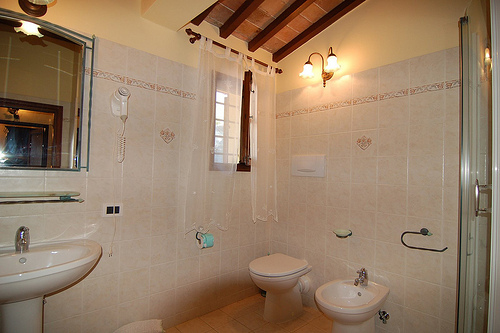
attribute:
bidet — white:
[318, 262, 393, 329]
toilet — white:
[240, 242, 313, 324]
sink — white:
[1, 217, 103, 332]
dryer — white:
[96, 76, 141, 169]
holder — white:
[325, 223, 356, 247]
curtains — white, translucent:
[197, 34, 279, 220]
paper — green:
[199, 233, 217, 250]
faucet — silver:
[12, 215, 45, 257]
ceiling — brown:
[174, 1, 383, 61]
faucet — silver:
[350, 263, 372, 288]